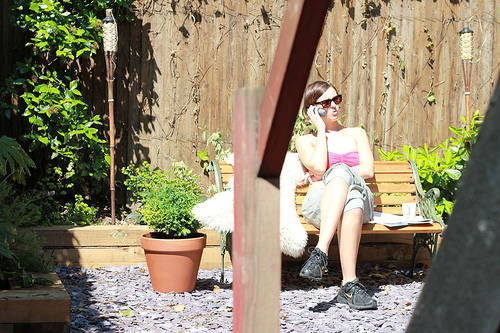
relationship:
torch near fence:
[99, 6, 117, 226] [114, 0, 499, 210]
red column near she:
[233, 3, 330, 331] [295, 81, 377, 310]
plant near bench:
[113, 160, 208, 290] [212, 145, 442, 284]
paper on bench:
[370, 212, 423, 229] [210, 155, 443, 293]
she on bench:
[295, 81, 377, 310] [210, 155, 443, 293]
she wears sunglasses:
[295, 81, 377, 310] [307, 93, 342, 108]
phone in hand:
[305, 104, 325, 114] [306, 102, 326, 127]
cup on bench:
[402, 200, 416, 219] [210, 155, 443, 293]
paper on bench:
[370, 210, 432, 228] [210, 155, 443, 293]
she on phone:
[295, 81, 377, 310] [308, 102, 326, 116]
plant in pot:
[121, 160, 208, 292] [138, 229, 215, 289]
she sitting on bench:
[295, 81, 377, 310] [210, 155, 443, 293]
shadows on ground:
[308, 285, 340, 315] [130, 286, 179, 331]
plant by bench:
[121, 160, 208, 292] [210, 155, 443, 293]